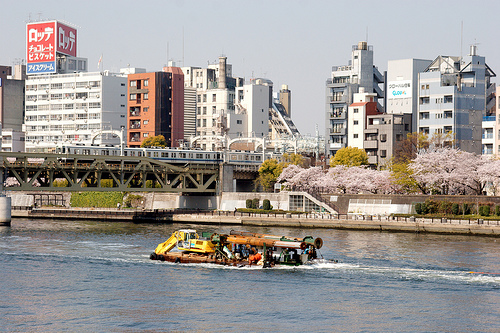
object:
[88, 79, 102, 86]
window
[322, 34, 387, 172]
building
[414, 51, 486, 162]
building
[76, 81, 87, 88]
window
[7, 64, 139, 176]
building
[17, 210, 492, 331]
water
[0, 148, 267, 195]
bridge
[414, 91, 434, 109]
window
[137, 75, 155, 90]
window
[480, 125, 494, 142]
window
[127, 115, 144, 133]
window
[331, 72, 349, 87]
window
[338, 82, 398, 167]
white building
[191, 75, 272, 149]
white building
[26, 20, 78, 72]
sign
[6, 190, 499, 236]
wall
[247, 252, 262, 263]
object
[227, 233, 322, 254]
pipe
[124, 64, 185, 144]
building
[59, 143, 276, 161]
train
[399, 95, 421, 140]
ground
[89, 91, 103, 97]
window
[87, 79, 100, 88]
window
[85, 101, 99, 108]
window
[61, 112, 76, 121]
window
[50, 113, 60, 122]
window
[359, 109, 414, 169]
building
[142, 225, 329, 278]
boat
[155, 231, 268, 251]
stuff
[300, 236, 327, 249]
pipe end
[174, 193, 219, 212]
shadow